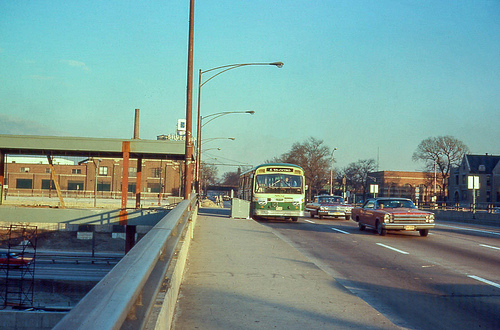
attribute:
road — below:
[0, 251, 104, 281]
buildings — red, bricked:
[0, 132, 500, 202]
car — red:
[346, 192, 436, 232]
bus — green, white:
[246, 158, 311, 219]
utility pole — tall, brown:
[179, 0, 200, 205]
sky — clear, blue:
[7, 0, 497, 194]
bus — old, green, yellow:
[238, 163, 308, 220]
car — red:
[349, 195, 438, 238]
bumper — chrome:
[385, 211, 436, 226]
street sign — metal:
[466, 173, 480, 212]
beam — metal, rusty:
[120, 137, 130, 226]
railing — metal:
[48, 192, 198, 329]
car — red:
[305, 195, 352, 222]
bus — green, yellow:
[239, 162, 309, 224]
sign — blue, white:
[175, 117, 187, 132]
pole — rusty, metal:
[183, 1, 195, 199]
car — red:
[1, 246, 33, 271]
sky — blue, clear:
[2, 1, 482, 177]